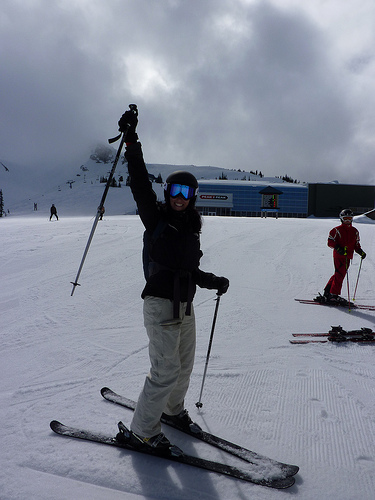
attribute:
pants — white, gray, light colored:
[129, 293, 197, 442]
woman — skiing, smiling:
[119, 111, 230, 454]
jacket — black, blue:
[123, 138, 212, 304]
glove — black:
[119, 107, 142, 147]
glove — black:
[207, 272, 228, 295]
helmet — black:
[161, 170, 200, 208]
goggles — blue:
[162, 180, 198, 201]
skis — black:
[50, 386, 302, 493]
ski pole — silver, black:
[68, 103, 139, 299]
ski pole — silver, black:
[193, 281, 222, 410]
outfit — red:
[323, 226, 361, 298]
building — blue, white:
[196, 180, 308, 215]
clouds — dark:
[2, 2, 374, 184]